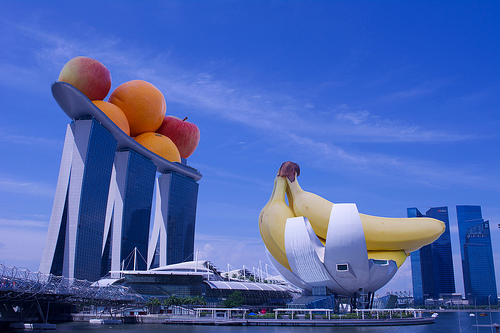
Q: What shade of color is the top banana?
A: Yellow.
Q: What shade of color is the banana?
A: Yellow.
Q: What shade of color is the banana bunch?
A: Yellow.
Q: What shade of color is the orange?
A: Orange.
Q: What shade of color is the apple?
A: Red.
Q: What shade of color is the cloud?
A: White.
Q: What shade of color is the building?
A: Gray.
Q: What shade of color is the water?
A: Blue.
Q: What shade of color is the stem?
A: Brown.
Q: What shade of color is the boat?
A: White.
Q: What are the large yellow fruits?
A: Bananas.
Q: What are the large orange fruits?
A: Oranges.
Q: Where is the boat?
A: Water.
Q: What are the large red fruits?
A: Apples.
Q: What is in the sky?
A: Clouds.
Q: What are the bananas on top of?
A: Building.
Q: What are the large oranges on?
A: Building.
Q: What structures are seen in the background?
A: Buildings.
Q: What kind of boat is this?
A: Cruise ship.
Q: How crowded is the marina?
A: Empty.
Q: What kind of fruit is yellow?
A: Banana.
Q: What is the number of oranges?
A: 3.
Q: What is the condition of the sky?
A: Cloudy.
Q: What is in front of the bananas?
A: Water.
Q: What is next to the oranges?
A: Apples.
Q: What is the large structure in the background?
A: Building.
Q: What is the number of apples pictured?
A: 2.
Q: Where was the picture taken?
A: Harbor.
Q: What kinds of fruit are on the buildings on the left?
A: Apples and oranges.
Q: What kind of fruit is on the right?
A: Bananas.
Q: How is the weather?
A: Sunny.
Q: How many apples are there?
A: Two.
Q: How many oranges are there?
A: Three.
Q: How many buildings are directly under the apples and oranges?
A: Three.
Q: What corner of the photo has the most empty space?
A: Upper right.